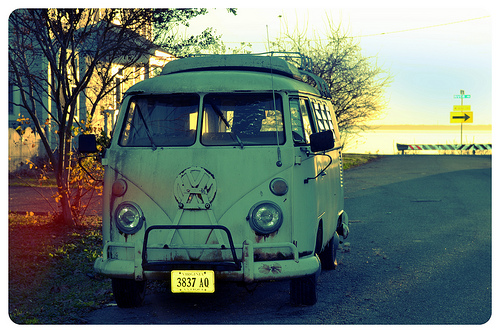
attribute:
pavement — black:
[295, 145, 490, 323]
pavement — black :
[121, 151, 494, 325]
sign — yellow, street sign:
[452, 104, 475, 131]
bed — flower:
[15, 226, 117, 320]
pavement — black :
[408, 226, 473, 301]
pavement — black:
[366, 175, 441, 227]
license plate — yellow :
[149, 259, 245, 308]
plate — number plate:
[151, 253, 226, 290]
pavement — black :
[323, 265, 358, 305]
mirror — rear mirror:
[154, 73, 290, 192]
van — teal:
[71, 30, 360, 312]